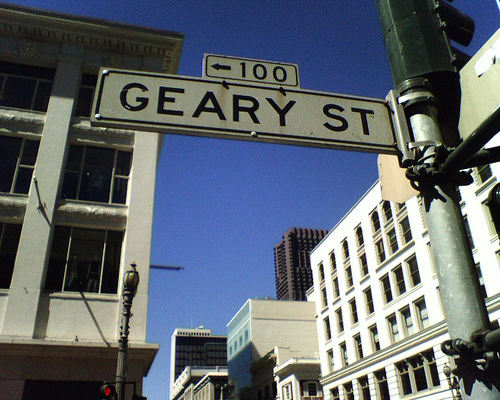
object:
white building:
[1, 2, 184, 399]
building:
[273, 225, 337, 300]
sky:
[0, 0, 499, 399]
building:
[170, 327, 225, 398]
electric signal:
[380, 0, 458, 104]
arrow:
[210, 60, 232, 73]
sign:
[90, 66, 398, 154]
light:
[106, 383, 114, 397]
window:
[367, 325, 381, 351]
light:
[103, 386, 113, 395]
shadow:
[78, 289, 113, 347]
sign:
[201, 53, 299, 92]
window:
[400, 303, 416, 335]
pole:
[396, 91, 499, 399]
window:
[331, 276, 341, 297]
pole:
[114, 293, 132, 398]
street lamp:
[121, 261, 141, 313]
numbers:
[239, 59, 246, 76]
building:
[0, 0, 184, 399]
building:
[308, 156, 499, 399]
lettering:
[118, 82, 149, 112]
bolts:
[413, 163, 434, 177]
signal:
[102, 385, 113, 397]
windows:
[65, 226, 110, 291]